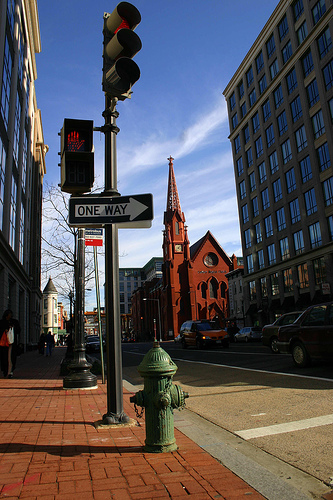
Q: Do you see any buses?
A: No, there are no buses.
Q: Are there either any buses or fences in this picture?
A: No, there are no buses or fences.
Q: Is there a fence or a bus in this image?
A: No, there are no buses or fences.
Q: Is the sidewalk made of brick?
A: Yes, the sidewalk is made of brick.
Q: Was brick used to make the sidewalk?
A: Yes, the sidewalk is made of brick.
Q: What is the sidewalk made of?
A: The sidewalk is made of brick.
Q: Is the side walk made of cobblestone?
A: No, the side walk is made of brick.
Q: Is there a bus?
A: No, there are no buses.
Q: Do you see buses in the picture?
A: No, there are no buses.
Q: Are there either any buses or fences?
A: No, there are no buses or fences.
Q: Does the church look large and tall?
A: Yes, the church is large and tall.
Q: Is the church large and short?
A: No, the church is large but tall.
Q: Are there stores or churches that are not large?
A: No, there is a church but it is large.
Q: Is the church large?
A: Yes, the church is large.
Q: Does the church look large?
A: Yes, the church is large.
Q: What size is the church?
A: The church is large.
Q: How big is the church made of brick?
A: The church is large.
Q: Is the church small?
A: No, the church is large.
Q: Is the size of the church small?
A: No, the church is large.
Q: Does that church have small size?
A: No, the church is large.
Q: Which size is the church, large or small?
A: The church is large.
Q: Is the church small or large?
A: The church is large.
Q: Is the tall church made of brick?
A: Yes, the church is made of brick.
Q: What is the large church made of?
A: The church is made of brick.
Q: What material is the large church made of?
A: The church is made of brick.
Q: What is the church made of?
A: The church is made of brick.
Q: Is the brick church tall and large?
A: Yes, the church is tall and large.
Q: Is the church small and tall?
A: No, the church is tall but large.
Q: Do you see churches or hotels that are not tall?
A: No, there is a church but it is tall.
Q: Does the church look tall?
A: Yes, the church is tall.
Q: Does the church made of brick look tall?
A: Yes, the church is tall.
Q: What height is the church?
A: The church is tall.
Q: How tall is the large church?
A: The church is tall.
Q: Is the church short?
A: No, the church is tall.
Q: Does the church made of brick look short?
A: No, the church is tall.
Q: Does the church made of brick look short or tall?
A: The church is tall.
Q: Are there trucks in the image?
A: No, there are no trucks.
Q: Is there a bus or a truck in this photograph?
A: No, there are no trucks or buses.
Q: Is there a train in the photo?
A: No, there are no trains.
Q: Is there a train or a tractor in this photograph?
A: No, there are no trains or tractors.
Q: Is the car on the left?
A: No, the car is on the right of the image.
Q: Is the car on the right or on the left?
A: The car is on the right of the image.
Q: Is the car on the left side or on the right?
A: The car is on the right of the image.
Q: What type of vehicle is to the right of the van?
A: The vehicle is a car.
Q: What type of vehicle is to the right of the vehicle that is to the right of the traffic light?
A: The vehicle is a car.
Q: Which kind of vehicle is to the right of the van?
A: The vehicle is a car.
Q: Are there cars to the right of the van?
A: Yes, there is a car to the right of the van.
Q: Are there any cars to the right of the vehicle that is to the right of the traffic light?
A: Yes, there is a car to the right of the van.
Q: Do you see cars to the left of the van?
A: No, the car is to the right of the van.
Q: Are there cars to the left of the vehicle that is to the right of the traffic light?
A: No, the car is to the right of the van.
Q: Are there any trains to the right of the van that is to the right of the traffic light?
A: No, there is a car to the right of the van.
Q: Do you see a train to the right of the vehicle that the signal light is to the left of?
A: No, there is a car to the right of the van.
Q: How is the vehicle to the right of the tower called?
A: The vehicle is a car.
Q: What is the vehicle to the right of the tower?
A: The vehicle is a car.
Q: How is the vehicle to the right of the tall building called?
A: The vehicle is a car.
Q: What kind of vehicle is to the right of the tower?
A: The vehicle is a car.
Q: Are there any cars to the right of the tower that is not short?
A: Yes, there is a car to the right of the tower.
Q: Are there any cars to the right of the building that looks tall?
A: Yes, there is a car to the right of the tower.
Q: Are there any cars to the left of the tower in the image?
A: No, the car is to the right of the tower.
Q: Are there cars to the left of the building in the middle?
A: No, the car is to the right of the tower.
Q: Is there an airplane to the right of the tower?
A: No, there is a car to the right of the tower.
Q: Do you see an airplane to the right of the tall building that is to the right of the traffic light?
A: No, there is a car to the right of the tower.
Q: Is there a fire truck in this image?
A: No, there are no fire trucks.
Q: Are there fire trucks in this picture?
A: No, there are no fire trucks.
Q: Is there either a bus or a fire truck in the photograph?
A: No, there are no fire trucks or buses.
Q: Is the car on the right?
A: Yes, the car is on the right of the image.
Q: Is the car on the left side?
A: No, the car is on the right of the image.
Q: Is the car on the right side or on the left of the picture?
A: The car is on the right of the image.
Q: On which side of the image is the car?
A: The car is on the right of the image.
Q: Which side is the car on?
A: The car is on the right of the image.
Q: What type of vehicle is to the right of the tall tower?
A: The vehicle is a car.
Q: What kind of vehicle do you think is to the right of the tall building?
A: The vehicle is a car.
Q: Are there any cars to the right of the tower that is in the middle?
A: Yes, there is a car to the right of the tower.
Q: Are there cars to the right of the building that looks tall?
A: Yes, there is a car to the right of the tower.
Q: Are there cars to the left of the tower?
A: No, the car is to the right of the tower.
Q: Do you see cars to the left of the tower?
A: No, the car is to the right of the tower.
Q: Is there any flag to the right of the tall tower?
A: No, there is a car to the right of the tower.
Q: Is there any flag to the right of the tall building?
A: No, there is a car to the right of the tower.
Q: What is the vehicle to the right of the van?
A: The vehicle is a car.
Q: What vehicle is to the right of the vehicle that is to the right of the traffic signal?
A: The vehicle is a car.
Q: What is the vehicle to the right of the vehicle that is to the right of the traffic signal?
A: The vehicle is a car.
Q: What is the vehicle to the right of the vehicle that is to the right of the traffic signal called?
A: The vehicle is a car.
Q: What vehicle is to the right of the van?
A: The vehicle is a car.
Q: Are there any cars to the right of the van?
A: Yes, there is a car to the right of the van.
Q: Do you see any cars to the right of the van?
A: Yes, there is a car to the right of the van.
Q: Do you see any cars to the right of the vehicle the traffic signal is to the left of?
A: Yes, there is a car to the right of the van.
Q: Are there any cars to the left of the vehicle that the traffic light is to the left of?
A: No, the car is to the right of the van.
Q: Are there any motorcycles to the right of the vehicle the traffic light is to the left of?
A: No, there is a car to the right of the van.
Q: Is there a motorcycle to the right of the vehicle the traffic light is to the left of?
A: No, there is a car to the right of the van.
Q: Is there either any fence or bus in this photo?
A: No, there are no buses or fences.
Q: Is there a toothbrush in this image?
A: No, there are no toothbrushes.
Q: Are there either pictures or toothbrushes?
A: No, there are no toothbrushes or pictures.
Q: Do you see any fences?
A: No, there are no fences.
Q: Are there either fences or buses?
A: No, there are no fences or buses.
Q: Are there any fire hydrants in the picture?
A: Yes, there is a fire hydrant.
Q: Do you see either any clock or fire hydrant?
A: Yes, there is a fire hydrant.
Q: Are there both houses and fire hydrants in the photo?
A: No, there is a fire hydrant but no houses.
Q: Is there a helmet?
A: No, there are no helmets.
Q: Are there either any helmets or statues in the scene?
A: No, there are no helmets or statues.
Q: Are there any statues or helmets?
A: No, there are no helmets or statues.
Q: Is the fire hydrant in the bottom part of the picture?
A: Yes, the fire hydrant is in the bottom of the image.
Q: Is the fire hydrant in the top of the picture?
A: No, the fire hydrant is in the bottom of the image.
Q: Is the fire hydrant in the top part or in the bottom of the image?
A: The fire hydrant is in the bottom of the image.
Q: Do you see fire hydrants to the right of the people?
A: Yes, there is a fire hydrant to the right of the people.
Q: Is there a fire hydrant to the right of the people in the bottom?
A: Yes, there is a fire hydrant to the right of the people.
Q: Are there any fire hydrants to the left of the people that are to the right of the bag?
A: No, the fire hydrant is to the right of the people.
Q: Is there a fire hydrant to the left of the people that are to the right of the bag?
A: No, the fire hydrant is to the right of the people.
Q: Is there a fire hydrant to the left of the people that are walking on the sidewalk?
A: No, the fire hydrant is to the right of the people.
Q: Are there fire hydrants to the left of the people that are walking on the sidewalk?
A: No, the fire hydrant is to the right of the people.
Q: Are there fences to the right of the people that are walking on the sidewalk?
A: No, there is a fire hydrant to the right of the people.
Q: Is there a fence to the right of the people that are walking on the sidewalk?
A: No, there is a fire hydrant to the right of the people.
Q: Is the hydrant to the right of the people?
A: Yes, the hydrant is to the right of the people.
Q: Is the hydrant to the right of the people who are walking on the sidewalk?
A: Yes, the hydrant is to the right of the people.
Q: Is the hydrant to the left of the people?
A: No, the hydrant is to the right of the people.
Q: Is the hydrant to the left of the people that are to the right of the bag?
A: No, the hydrant is to the right of the people.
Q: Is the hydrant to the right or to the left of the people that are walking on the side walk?
A: The hydrant is to the right of the people.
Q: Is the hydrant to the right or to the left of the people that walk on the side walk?
A: The hydrant is to the right of the people.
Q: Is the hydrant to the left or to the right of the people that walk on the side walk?
A: The hydrant is to the right of the people.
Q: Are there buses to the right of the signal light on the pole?
A: No, there is a fire hydrant to the right of the traffic light.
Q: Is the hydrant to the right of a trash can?
A: No, the hydrant is to the right of the signal light.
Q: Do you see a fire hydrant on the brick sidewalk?
A: Yes, there is a fire hydrant on the sidewalk.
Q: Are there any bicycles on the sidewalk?
A: No, there is a fire hydrant on the sidewalk.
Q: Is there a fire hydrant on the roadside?
A: Yes, there is a fire hydrant on the roadside.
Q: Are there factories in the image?
A: No, there are no factories.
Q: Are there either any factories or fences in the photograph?
A: No, there are no factories or fences.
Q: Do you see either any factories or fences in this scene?
A: No, there are no factories or fences.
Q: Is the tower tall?
A: Yes, the tower is tall.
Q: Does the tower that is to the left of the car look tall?
A: Yes, the tower is tall.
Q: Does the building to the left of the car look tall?
A: Yes, the tower is tall.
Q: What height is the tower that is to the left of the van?
A: The tower is tall.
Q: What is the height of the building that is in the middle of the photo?
A: The tower is tall.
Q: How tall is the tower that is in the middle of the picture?
A: The tower is tall.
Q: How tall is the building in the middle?
A: The tower is tall.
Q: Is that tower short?
A: No, the tower is tall.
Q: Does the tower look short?
A: No, the tower is tall.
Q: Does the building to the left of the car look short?
A: No, the tower is tall.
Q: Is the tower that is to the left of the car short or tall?
A: The tower is tall.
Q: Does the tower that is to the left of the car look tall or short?
A: The tower is tall.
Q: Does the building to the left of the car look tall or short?
A: The tower is tall.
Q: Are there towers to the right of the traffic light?
A: Yes, there is a tower to the right of the traffic light.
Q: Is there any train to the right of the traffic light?
A: No, there is a tower to the right of the traffic light.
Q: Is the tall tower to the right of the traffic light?
A: Yes, the tower is to the right of the traffic light.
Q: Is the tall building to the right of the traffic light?
A: Yes, the tower is to the right of the traffic light.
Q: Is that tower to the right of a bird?
A: No, the tower is to the right of the traffic light.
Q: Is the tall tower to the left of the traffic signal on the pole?
A: No, the tower is to the right of the signal light.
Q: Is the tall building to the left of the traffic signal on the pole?
A: No, the tower is to the right of the signal light.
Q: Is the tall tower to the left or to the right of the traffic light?
A: The tower is to the right of the traffic light.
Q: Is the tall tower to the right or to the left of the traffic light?
A: The tower is to the right of the traffic light.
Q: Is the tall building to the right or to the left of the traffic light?
A: The tower is to the right of the traffic light.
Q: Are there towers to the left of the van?
A: Yes, there is a tower to the left of the van.